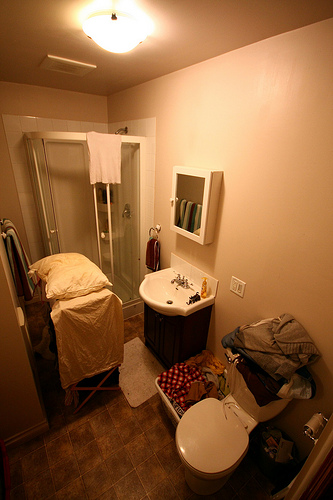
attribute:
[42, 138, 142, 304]
door — glass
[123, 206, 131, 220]
water handle — metallic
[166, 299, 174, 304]
drain hole — silver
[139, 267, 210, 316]
basin — white, porcelain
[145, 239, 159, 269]
hand towel — hanging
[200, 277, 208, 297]
soap bottle — liquid, yellow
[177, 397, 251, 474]
toilet cover — closed, white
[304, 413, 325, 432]
toilet roll — white, empty, cardboard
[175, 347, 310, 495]
toilet — white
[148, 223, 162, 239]
towel holder — silver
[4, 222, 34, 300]
towel — colorful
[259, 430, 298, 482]
trash can — full, black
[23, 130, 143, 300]
shower — tall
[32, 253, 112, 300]
pillow — white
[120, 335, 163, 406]
rug — light colored, slightly dirty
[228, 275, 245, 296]
light switch — white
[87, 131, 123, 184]
towel — white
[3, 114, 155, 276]
bath tile — terra cotta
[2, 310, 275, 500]
floor — brown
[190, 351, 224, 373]
garment — yellow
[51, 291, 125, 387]
sheet — white